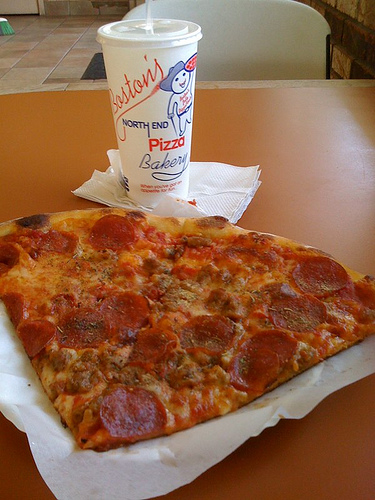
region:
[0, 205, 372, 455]
Two slices of pepperoni and sausage pizza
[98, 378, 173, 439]
Pepperoni slice on pizza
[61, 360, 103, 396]
Italian slice on pizza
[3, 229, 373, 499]
Greasy white paper holding pizza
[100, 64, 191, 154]
Boston's North End Pizza logo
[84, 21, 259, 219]
Cup on white napkin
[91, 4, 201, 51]
Clear straw and cap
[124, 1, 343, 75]
White plastic table chair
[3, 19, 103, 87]
Light brown floor tiling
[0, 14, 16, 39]
Edge of green bristled floor broom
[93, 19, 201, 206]
a paper drinking cup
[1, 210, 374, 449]
two slices of pepperoni sausage pizza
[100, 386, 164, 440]
a red slice of pepperoni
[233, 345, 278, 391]
a red slice of pepperoni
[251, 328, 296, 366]
a red slice of pepperoni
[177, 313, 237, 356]
a red slice of pepperoni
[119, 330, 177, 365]
a red slice of pepperoni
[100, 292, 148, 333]
a red slice of pepperoni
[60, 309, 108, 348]
a red slice of pepperoni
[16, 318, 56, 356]
a red slice of pepperoni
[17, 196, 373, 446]
a pizza on a table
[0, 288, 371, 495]
a napkin under the pizza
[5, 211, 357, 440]
pepperoni on the pizza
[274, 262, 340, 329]
herbs on pepperoni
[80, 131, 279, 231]
a napkin behind the pizza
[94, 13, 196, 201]
a glass on the napkin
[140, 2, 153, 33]
a straw in the glass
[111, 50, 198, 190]
a design on the glass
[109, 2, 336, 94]
a chair behind the table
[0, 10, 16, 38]
the corner of a broom on the floor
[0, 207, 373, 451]
Two slices of pizza sitting on napkin.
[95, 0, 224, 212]
The cup has a top and a straw.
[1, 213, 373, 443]
The pizza has pepperoni on it.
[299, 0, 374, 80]
Bricks are on the wall.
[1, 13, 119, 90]
Tile is on the floor.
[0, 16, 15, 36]
The bristles are green with a white top.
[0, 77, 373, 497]
The food and drink are on a orange surface.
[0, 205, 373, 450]
The Pizza with meat, crust and cheese.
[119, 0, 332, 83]
White chair is against table edge.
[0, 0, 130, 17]
Three tiles in wall next to door.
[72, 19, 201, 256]
a paper drink cup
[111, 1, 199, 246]
a cup and straw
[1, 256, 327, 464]
two slices of pizza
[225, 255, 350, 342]
slices of pepperoni on a pizza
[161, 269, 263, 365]
melted cheese on a pizza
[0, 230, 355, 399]
two slices of cooked pizza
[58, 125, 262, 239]
a cup sitting on a napkin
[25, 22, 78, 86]
a tile floor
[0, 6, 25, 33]
a green broom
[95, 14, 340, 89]
a plastic chair at a table